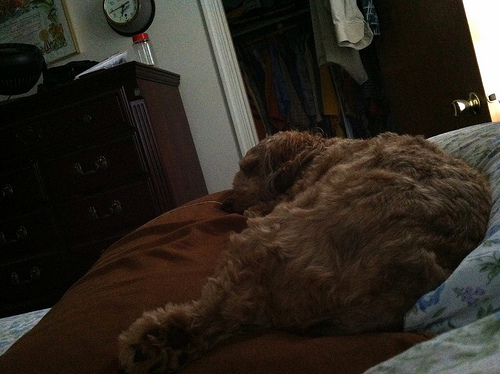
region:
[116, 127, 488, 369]
dog laying on the bed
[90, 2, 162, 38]
clock on the wall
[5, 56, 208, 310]
dark brown dresser against the wall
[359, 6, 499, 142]
door is hanging open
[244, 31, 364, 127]
clothing hanging in the closet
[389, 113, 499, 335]
flower design on the pillow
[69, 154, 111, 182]
gold handle on the drawer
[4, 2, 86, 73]
gold frame hanging on the wall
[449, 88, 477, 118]
doorknob on the closet door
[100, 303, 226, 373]
bottom of the paw is black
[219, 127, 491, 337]
brown dog sleeping on pillows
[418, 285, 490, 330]
pillow case has blue and purple flowers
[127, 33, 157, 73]
clear container with red lid on edge of dresser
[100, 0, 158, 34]
clock hanging on the wall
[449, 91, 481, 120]
door knob made of metal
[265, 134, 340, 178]
dog's brown fur is curly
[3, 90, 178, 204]
dresser made of dark cherry wood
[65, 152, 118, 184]
metal handle of the dresser draw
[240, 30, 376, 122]
clothes hanging in the closet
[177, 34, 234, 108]
wall in painted white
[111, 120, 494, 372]
A dog lying on a bed.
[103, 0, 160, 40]
A partially obscured clock on the wall.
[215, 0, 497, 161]
An open closet filled with clothes.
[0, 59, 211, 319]
A dark wooden dresser.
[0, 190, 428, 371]
Red sheets on a bed.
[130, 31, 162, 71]
A plastic container with a red top.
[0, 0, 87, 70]
A framed certificate on the wall.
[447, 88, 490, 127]
A gold doorknob.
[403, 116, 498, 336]
A pillow with flowers on it.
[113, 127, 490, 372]
A furry brown dog.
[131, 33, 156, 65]
red and clear water bottle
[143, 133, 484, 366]
brown furry dog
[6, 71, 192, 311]
cherry wood tall dresser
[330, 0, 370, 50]
sleeve of white shirt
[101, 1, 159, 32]
round grey and white wall clock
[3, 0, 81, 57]
framed picture hanging on wall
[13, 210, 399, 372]
brown blanket on bed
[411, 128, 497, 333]
white and floral pillow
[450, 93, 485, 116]
metal door handle to closet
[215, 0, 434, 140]
bedroom closet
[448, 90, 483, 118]
door handle on door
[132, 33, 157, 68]
plastic bottle on table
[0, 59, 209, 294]
dark wooden cabinet in room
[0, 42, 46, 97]
black fan on desk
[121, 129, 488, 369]
dog laying on bed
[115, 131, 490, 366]
brown dog laying on bed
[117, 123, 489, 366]
brown dog with eyes closed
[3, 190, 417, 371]
brown blanket under dog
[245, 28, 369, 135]
clothes hanging in closet